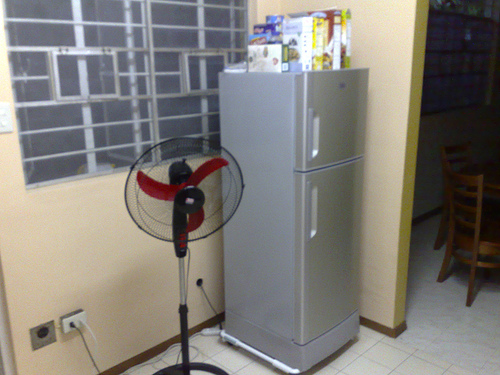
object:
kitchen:
[0, 0, 499, 374]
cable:
[79, 322, 107, 367]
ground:
[407, 223, 444, 287]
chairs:
[434, 169, 500, 306]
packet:
[282, 16, 313, 71]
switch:
[0, 102, 14, 132]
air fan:
[121, 137, 258, 375]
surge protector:
[201, 327, 221, 337]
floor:
[122, 271, 498, 375]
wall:
[1, 0, 281, 372]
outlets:
[28, 319, 57, 350]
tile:
[361, 341, 410, 370]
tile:
[209, 346, 251, 373]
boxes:
[247, 44, 282, 73]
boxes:
[347, 6, 351, 69]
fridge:
[212, 67, 376, 373]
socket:
[61, 310, 88, 333]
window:
[3, 0, 261, 188]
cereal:
[272, 57, 278, 65]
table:
[461, 157, 500, 190]